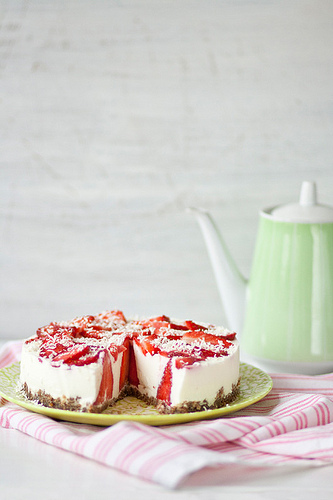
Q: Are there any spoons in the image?
A: No, there are no spoons.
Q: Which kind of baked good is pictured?
A: The baked good is a pie.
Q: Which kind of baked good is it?
A: The food is a pie.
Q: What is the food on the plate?
A: The food is a pie.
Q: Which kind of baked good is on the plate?
A: The food is a pie.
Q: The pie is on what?
A: The pie is on the plate.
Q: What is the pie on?
A: The pie is on the plate.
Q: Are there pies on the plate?
A: Yes, there is a pie on the plate.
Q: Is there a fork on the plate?
A: No, there is a pie on the plate.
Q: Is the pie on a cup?
A: No, the pie is on a plate.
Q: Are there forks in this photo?
A: No, there are no forks.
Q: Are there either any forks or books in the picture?
A: No, there are no forks or books.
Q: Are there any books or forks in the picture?
A: No, there are no forks or books.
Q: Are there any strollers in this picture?
A: No, there are no strollers.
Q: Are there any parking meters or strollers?
A: No, there are no strollers or parking meters.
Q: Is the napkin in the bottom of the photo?
A: Yes, the napkin is in the bottom of the image.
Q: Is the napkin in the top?
A: No, the napkin is in the bottom of the image.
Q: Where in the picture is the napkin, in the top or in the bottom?
A: The napkin is in the bottom of the image.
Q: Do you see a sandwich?
A: No, there are no sandwiches.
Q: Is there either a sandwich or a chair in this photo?
A: No, there are no sandwiches or chairs.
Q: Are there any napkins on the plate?
A: Yes, there is a napkin on the plate.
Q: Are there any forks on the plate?
A: No, there is a napkin on the plate.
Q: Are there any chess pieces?
A: No, there are no chess pieces.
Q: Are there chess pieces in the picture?
A: No, there are no chess pieces.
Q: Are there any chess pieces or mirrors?
A: No, there are no chess pieces or mirrors.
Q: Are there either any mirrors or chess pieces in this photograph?
A: No, there are no chess pieces or mirrors.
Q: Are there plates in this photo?
A: Yes, there is a plate.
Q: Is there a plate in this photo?
A: Yes, there is a plate.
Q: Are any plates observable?
A: Yes, there is a plate.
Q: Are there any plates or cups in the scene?
A: Yes, there is a plate.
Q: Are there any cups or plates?
A: Yes, there is a plate.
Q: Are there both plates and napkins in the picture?
A: Yes, there are both a plate and a napkin.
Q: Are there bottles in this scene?
A: No, there are no bottles.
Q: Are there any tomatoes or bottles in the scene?
A: No, there are no bottles or tomatoes.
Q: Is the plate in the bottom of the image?
A: Yes, the plate is in the bottom of the image.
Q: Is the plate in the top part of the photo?
A: No, the plate is in the bottom of the image.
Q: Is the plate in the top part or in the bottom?
A: The plate is in the bottom of the image.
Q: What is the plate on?
A: The plate is on the napkin.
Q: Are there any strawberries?
A: Yes, there is a strawberry.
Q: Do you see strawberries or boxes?
A: Yes, there is a strawberry.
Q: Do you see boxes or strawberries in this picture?
A: Yes, there is a strawberry.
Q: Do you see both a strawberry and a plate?
A: Yes, there are both a strawberry and a plate.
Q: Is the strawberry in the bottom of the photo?
A: Yes, the strawberry is in the bottom of the image.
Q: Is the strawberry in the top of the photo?
A: No, the strawberry is in the bottom of the image.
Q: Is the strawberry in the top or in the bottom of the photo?
A: The strawberry is in the bottom of the image.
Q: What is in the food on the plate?
A: The strawberry is in the pie.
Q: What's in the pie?
A: The strawberry is in the pie.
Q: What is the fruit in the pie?
A: The fruit is a strawberry.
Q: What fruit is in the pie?
A: The fruit is a strawberry.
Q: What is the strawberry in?
A: The strawberry is in the pie.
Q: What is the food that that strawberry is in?
A: The food is a pie.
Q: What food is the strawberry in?
A: The strawberry is in the pie.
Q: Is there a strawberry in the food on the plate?
A: Yes, there is a strawberry in the pie.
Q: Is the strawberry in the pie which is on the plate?
A: Yes, the strawberry is in the pie.